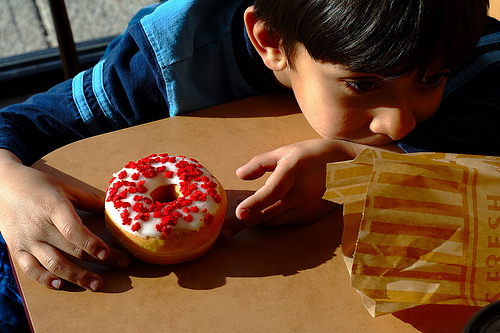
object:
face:
[277, 41, 452, 147]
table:
[2, 85, 500, 332]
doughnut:
[102, 152, 228, 265]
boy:
[0, 0, 499, 330]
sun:
[107, 188, 348, 290]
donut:
[104, 151, 229, 265]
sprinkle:
[103, 151, 221, 238]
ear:
[241, 4, 291, 71]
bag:
[320, 145, 499, 318]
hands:
[220, 139, 358, 239]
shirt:
[0, 0, 499, 168]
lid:
[466, 299, 499, 332]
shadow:
[57, 189, 343, 295]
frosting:
[124, 212, 166, 239]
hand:
[0, 158, 131, 292]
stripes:
[71, 59, 119, 127]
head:
[242, 0, 494, 147]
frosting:
[123, 183, 147, 203]